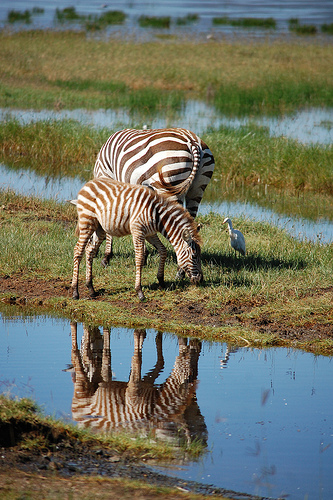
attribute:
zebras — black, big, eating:
[60, 119, 228, 304]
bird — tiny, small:
[215, 217, 258, 262]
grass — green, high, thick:
[8, 21, 332, 344]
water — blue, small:
[5, 290, 332, 496]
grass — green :
[12, 42, 322, 488]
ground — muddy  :
[5, 39, 316, 493]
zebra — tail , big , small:
[63, 118, 231, 303]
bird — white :
[220, 211, 253, 264]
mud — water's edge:
[29, 430, 156, 486]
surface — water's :
[21, 96, 313, 138]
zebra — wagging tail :
[86, 124, 217, 216]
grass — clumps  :
[23, 204, 319, 332]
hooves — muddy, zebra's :
[68, 274, 166, 307]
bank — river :
[9, 274, 303, 352]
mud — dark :
[14, 275, 40, 296]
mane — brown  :
[157, 185, 204, 241]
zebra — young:
[58, 113, 224, 305]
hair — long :
[155, 182, 204, 242]